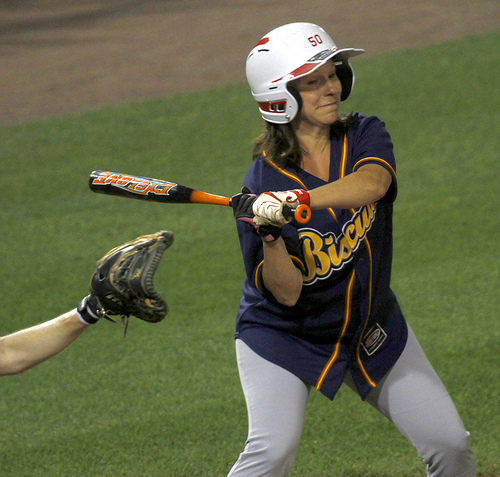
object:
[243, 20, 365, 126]
helmet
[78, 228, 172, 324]
hand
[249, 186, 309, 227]
glove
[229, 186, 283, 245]
glove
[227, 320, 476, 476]
pants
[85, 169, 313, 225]
bat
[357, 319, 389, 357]
label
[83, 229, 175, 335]
glove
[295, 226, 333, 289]
b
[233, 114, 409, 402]
jersey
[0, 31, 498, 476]
grass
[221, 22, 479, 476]
player